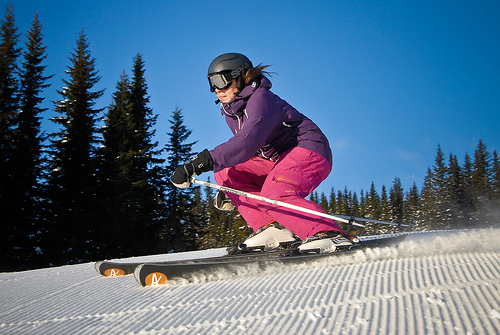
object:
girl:
[170, 52, 361, 255]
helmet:
[207, 52, 250, 105]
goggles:
[205, 61, 254, 94]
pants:
[215, 146, 348, 240]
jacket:
[208, 75, 333, 173]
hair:
[242, 62, 279, 87]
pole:
[190, 176, 367, 229]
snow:
[2, 230, 498, 335]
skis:
[133, 244, 400, 288]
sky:
[1, 0, 499, 204]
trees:
[45, 27, 110, 268]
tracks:
[2, 275, 340, 334]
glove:
[170, 148, 216, 189]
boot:
[241, 221, 298, 252]